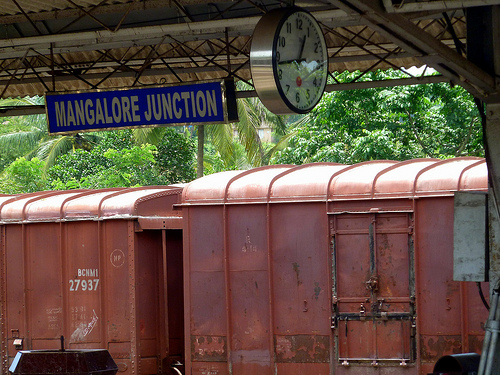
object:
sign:
[41, 82, 227, 137]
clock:
[249, 5, 332, 116]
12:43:
[271, 11, 328, 114]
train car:
[2, 163, 497, 373]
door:
[327, 208, 417, 369]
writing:
[66, 278, 75, 291]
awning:
[0, 1, 499, 100]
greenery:
[0, 58, 486, 194]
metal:
[246, 6, 330, 115]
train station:
[2, 2, 496, 375]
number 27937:
[66, 278, 99, 293]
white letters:
[75, 265, 101, 280]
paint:
[275, 333, 331, 367]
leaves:
[268, 67, 483, 152]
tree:
[245, 61, 490, 162]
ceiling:
[0, 1, 498, 101]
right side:
[247, 2, 494, 374]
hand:
[299, 31, 308, 62]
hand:
[276, 52, 308, 66]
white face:
[274, 11, 329, 111]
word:
[204, 91, 220, 121]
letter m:
[52, 97, 68, 128]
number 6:
[293, 90, 302, 107]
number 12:
[293, 17, 304, 32]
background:
[0, 0, 495, 195]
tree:
[48, 121, 194, 188]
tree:
[195, 82, 286, 185]